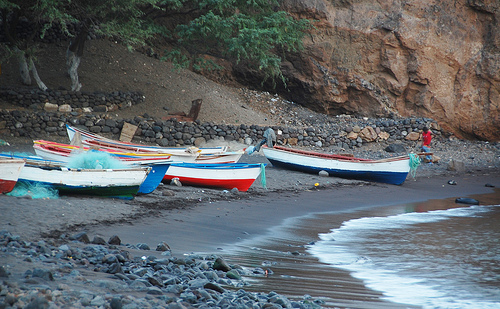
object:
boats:
[0, 158, 24, 195]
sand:
[0, 193, 140, 239]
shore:
[114, 178, 499, 262]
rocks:
[0, 293, 46, 309]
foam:
[304, 206, 500, 309]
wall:
[4, 0, 500, 150]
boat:
[262, 144, 417, 185]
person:
[421, 126, 436, 164]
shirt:
[422, 131, 432, 145]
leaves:
[172, 9, 319, 91]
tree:
[41, 0, 320, 91]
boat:
[32, 139, 266, 192]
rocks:
[58, 104, 73, 112]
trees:
[0, 0, 188, 91]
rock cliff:
[152, 0, 500, 143]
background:
[1, 0, 499, 145]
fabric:
[260, 163, 267, 189]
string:
[409, 153, 422, 182]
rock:
[68, 231, 91, 244]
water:
[305, 192, 500, 309]